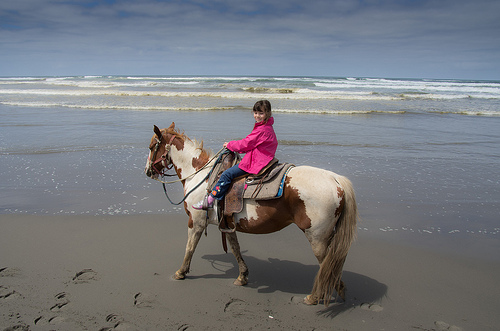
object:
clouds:
[0, 0, 499, 80]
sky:
[0, 1, 498, 78]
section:
[0, 128, 172, 216]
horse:
[145, 122, 357, 305]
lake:
[0, 75, 499, 232]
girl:
[190, 100, 277, 211]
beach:
[0, 212, 499, 330]